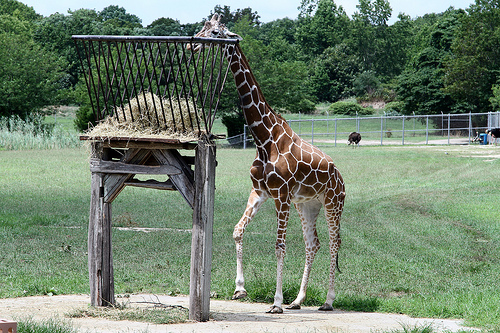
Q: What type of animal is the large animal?
A: A giraffe.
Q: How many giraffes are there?
A: One.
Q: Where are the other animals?
A: Behind the giraffe.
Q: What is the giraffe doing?
A: Eating.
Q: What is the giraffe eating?
A: Hay.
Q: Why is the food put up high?
A: So the giraffe can reach it.